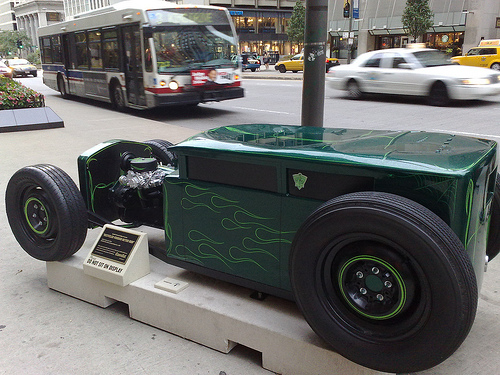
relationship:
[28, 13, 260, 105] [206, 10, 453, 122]
bus on street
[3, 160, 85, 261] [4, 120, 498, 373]
small wheel on car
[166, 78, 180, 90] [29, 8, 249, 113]
light on bus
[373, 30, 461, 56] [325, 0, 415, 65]
windows on building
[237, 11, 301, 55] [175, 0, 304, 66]
windows on building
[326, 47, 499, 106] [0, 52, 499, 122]
car in traffic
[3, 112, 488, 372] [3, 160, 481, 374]
motorbox has tires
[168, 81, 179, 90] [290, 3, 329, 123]
light on bus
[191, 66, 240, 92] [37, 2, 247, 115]
sign on bus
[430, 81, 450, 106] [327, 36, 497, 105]
tire on car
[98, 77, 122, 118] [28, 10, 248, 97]
tire on bus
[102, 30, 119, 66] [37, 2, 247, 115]
window on bus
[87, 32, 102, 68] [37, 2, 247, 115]
window on bus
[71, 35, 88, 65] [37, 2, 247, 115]
window on bus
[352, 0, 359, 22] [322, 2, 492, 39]
sign on building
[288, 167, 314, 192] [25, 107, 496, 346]
sticker on car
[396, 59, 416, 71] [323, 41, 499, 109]
mirror on car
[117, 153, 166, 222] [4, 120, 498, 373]
engine in car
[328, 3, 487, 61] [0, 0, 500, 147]
store across city street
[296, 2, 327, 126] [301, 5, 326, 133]
pole near street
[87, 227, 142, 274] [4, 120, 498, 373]
plaque near car